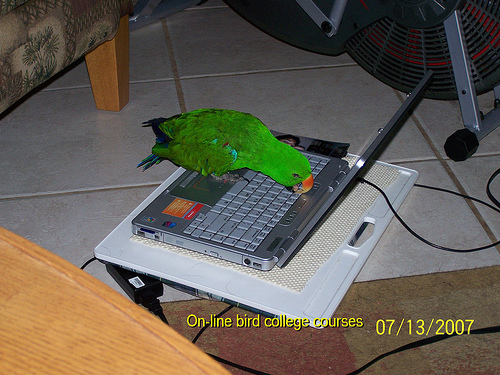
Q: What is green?
A: The parrot.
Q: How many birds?
A: One.